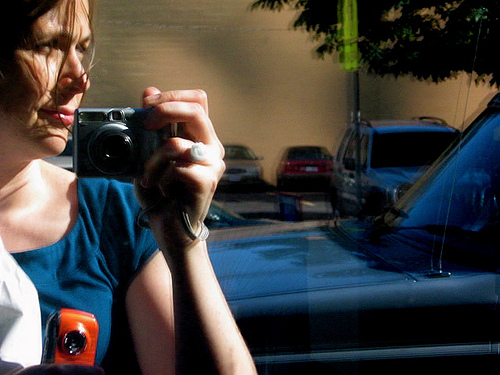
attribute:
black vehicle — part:
[203, 107, 498, 364]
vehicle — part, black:
[274, 97, 494, 368]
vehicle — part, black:
[207, 88, 498, 373]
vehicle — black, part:
[201, 93, 490, 333]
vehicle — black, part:
[259, 104, 480, 370]